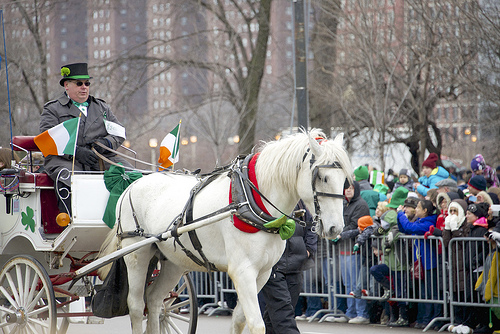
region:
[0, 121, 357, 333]
A white horse pulling a white carriage.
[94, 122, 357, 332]
White horse with a green bow on its harness.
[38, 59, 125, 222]
Carriage driver in a tophat.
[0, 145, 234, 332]
White carriage with green decorations on it.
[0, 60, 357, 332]
Horse pulling a carriage decorated for St. Patrick's Day.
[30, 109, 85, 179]
Irish flag.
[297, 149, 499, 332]
Spectators watching a parade.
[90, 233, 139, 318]
Black bag to catch horse manure.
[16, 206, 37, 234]
A shamrock.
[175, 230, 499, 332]
Fence to keep bystanders off the street.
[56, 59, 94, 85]
black top hat with green accents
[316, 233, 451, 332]
metal barrier for crowd control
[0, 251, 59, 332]
white wagon wheel with black rubber tread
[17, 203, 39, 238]
green shamrock on a white background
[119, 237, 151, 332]
right back leg of a white horse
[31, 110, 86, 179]
small Irish flag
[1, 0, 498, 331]
people watching a St. Patrick's Day parade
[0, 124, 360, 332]
white horse pulling a white carriage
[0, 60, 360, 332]
man sitting in a white carriage being pulled by a horse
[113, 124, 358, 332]
horse wearing a green bow tie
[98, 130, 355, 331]
a white horse pulling a carriage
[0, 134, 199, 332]
a white carriage with red seats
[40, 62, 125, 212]
a man wearing a grey coat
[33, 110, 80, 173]
a small Irish flag on carriage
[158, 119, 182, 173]
a small Irish flag on carriage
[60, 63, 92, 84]
a black top hat with green accents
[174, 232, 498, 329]
grey metal crowd barrier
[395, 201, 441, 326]
a girl in a blue jacket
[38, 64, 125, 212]
a man driving a carriage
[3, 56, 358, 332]
horse is pulling a carriage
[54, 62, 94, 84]
man's top hat is black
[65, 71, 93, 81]
green trim on hat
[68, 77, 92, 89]
man is wearing sunglasses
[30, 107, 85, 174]
the flag is green orange and white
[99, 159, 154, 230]
the bow tie is green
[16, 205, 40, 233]
green clover on the carriage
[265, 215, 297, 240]
green bow tie on horse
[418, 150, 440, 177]
boy wearing a red hat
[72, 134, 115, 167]
man wearing black gloves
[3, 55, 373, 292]
a man in a carriage being pulled by a horse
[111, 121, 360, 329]
a horse pulling a carriage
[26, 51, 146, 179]
a carriage driver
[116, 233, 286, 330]
the legs of a horse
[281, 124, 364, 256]
the head of a horse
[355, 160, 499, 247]
several people at a parade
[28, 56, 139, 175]
a man wearing a hat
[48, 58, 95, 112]
a man wearing sunglasses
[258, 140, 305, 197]
the mane of a horse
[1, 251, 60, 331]
the wheel of a carriage